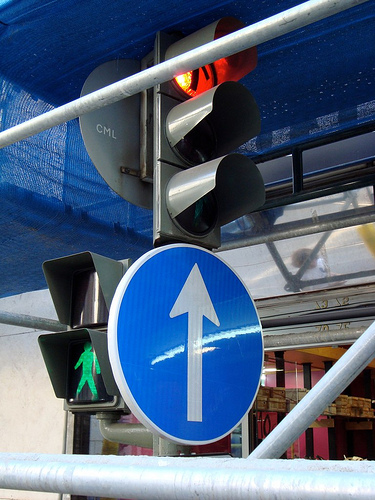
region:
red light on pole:
[152, 37, 231, 111]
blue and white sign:
[129, 269, 240, 436]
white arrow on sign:
[120, 270, 240, 436]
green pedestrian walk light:
[33, 258, 118, 416]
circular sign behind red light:
[87, 88, 156, 201]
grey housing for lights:
[169, 29, 229, 230]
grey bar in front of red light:
[1, 0, 354, 176]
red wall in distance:
[266, 355, 324, 458]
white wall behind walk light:
[8, 339, 60, 493]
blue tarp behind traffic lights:
[2, 17, 335, 285]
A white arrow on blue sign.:
[145, 233, 245, 433]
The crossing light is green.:
[55, 340, 111, 394]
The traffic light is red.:
[159, 17, 267, 87]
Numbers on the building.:
[314, 316, 361, 344]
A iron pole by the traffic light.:
[67, 43, 325, 92]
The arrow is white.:
[173, 267, 223, 413]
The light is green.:
[66, 345, 105, 401]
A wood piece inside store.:
[254, 378, 372, 409]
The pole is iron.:
[58, 449, 359, 487]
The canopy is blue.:
[18, 123, 129, 229]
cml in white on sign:
[90, 122, 120, 143]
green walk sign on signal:
[63, 338, 104, 394]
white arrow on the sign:
[171, 258, 221, 430]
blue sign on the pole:
[105, 239, 265, 441]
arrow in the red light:
[190, 57, 212, 87]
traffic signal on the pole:
[149, 15, 263, 243]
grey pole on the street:
[254, 318, 373, 463]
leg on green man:
[68, 378, 85, 397]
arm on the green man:
[75, 352, 85, 371]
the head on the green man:
[82, 338, 92, 352]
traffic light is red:
[153, 37, 233, 112]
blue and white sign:
[87, 217, 255, 436]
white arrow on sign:
[148, 289, 252, 442]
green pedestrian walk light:
[58, 265, 112, 401]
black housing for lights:
[43, 266, 109, 398]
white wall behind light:
[14, 353, 49, 444]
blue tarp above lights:
[24, 113, 78, 269]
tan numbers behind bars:
[311, 313, 359, 339]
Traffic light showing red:
[143, 21, 271, 244]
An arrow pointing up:
[171, 263, 219, 421]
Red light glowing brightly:
[165, 17, 220, 98]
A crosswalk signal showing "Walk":
[38, 249, 130, 409]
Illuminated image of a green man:
[69, 336, 107, 401]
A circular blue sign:
[111, 242, 264, 447]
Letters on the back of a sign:
[96, 123, 119, 139]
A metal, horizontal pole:
[1, 445, 373, 492]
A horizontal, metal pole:
[0, 0, 364, 158]